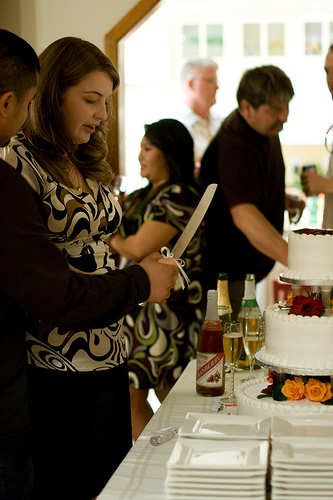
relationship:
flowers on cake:
[262, 369, 331, 407] [235, 227, 333, 417]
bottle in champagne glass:
[217, 273, 233, 334] [220, 317, 243, 405]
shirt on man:
[1, 149, 148, 397] [1, 28, 180, 492]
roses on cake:
[278, 375, 332, 404] [233, 218, 331, 429]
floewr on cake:
[283, 285, 319, 314] [256, 294, 332, 375]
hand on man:
[140, 244, 198, 308] [2, 56, 115, 337]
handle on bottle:
[221, 366, 238, 399] [195, 290, 225, 398]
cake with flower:
[254, 303, 333, 377] [255, 378, 316, 409]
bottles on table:
[196, 261, 280, 381] [131, 360, 286, 493]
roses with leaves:
[278, 375, 332, 404] [256, 383, 286, 399]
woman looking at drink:
[19, 24, 129, 476] [223, 318, 243, 415]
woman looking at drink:
[19, 24, 129, 476] [237, 307, 264, 393]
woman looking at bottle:
[19, 24, 129, 476] [195, 290, 225, 398]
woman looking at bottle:
[119, 106, 216, 441] [217, 273, 233, 334]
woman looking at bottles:
[119, 106, 216, 441] [236, 273, 262, 370]